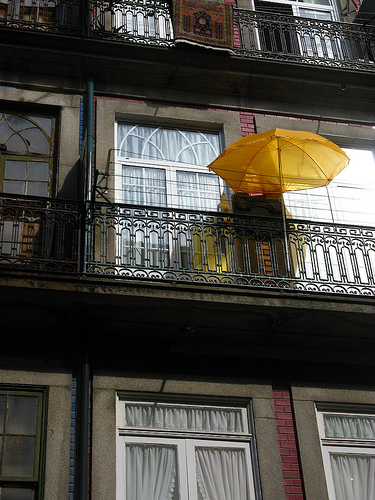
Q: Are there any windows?
A: Yes, there is a window.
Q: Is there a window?
A: Yes, there is a window.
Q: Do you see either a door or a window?
A: Yes, there is a window.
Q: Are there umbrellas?
A: Yes, there is an umbrella.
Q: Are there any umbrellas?
A: Yes, there is an umbrella.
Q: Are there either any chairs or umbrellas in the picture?
A: Yes, there is an umbrella.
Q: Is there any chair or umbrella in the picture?
A: Yes, there is an umbrella.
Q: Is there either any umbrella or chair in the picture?
A: Yes, there is an umbrella.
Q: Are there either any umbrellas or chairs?
A: Yes, there is an umbrella.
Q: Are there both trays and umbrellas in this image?
A: No, there is an umbrella but no trays.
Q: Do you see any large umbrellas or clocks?
A: Yes, there is a large umbrella.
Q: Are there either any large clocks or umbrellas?
A: Yes, there is a large umbrella.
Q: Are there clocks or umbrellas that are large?
A: Yes, the umbrella is large.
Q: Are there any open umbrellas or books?
A: Yes, there is an open umbrella.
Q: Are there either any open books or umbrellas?
A: Yes, there is an open umbrella.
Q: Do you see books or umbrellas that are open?
A: Yes, the umbrella is open.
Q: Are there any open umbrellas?
A: Yes, there is an open umbrella.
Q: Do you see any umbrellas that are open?
A: Yes, there is an umbrella that is open.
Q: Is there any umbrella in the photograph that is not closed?
A: Yes, there is a open umbrella.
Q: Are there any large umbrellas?
A: Yes, there is a large umbrella.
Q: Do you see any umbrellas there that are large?
A: Yes, there is an umbrella that is large.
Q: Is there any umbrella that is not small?
A: Yes, there is a large umbrella.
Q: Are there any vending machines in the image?
A: No, there are no vending machines.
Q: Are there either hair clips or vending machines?
A: No, there are no vending machines or hair clips.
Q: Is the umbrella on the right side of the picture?
A: Yes, the umbrella is on the right of the image.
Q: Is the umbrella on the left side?
A: No, the umbrella is on the right of the image.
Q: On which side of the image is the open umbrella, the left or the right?
A: The umbrella is on the right of the image.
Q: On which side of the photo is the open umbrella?
A: The umbrella is on the right of the image.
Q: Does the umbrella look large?
A: Yes, the umbrella is large.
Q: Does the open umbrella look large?
A: Yes, the umbrella is large.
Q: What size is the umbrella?
A: The umbrella is large.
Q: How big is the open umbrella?
A: The umbrella is large.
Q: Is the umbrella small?
A: No, the umbrella is large.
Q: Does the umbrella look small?
A: No, the umbrella is large.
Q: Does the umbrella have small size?
A: No, the umbrella is large.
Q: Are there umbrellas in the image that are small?
A: No, there is an umbrella but it is large.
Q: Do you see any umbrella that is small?
A: No, there is an umbrella but it is large.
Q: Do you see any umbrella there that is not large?
A: No, there is an umbrella but it is large.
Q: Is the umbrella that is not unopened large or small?
A: The umbrella is large.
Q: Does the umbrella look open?
A: Yes, the umbrella is open.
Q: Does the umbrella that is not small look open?
A: Yes, the umbrella is open.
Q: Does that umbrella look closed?
A: No, the umbrella is open.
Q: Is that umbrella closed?
A: No, the umbrella is open.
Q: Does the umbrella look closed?
A: No, the umbrella is open.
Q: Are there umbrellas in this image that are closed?
A: No, there is an umbrella but it is open.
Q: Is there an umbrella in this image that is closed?
A: No, there is an umbrella but it is open.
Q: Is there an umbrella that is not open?
A: No, there is an umbrella but it is open.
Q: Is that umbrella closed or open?
A: The umbrella is open.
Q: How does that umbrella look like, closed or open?
A: The umbrella is open.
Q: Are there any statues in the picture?
A: No, there are no statues.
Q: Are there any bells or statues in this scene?
A: No, there are no statues or bells.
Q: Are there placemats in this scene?
A: No, there are no placemats.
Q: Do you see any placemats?
A: No, there are no placemats.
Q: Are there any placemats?
A: No, there are no placemats.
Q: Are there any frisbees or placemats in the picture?
A: No, there are no placemats or frisbees.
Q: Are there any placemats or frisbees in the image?
A: No, there are no placemats or frisbees.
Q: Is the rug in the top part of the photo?
A: Yes, the rug is in the top of the image.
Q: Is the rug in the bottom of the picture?
A: No, the rug is in the top of the image.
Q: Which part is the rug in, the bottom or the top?
A: The rug is in the top of the image.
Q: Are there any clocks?
A: No, there are no clocks.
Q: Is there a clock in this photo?
A: No, there are no clocks.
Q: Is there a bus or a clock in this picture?
A: No, there are no clocks or buses.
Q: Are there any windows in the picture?
A: Yes, there are windows.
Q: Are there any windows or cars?
A: Yes, there are windows.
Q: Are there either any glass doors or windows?
A: Yes, there are glass windows.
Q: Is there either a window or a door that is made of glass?
A: Yes, the windows are made of glass.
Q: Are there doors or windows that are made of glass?
A: Yes, the windows are made of glass.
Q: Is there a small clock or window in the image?
A: Yes, there are small windows.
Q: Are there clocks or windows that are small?
A: Yes, the windows are small.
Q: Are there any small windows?
A: Yes, there are small windows.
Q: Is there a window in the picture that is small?
A: Yes, there are windows that are small.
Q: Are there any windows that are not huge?
A: Yes, there are small windows.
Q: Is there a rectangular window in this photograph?
A: Yes, there are rectangular windows.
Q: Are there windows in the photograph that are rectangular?
A: Yes, there are windows that are rectangular.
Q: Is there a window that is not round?
A: Yes, there are rectangular windows.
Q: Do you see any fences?
A: No, there are no fences.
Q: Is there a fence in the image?
A: No, there are no fences.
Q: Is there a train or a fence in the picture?
A: No, there are no fences or trains.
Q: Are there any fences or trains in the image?
A: No, there are no fences or trains.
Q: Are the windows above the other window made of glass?
A: Yes, the windows are made of glass.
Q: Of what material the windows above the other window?
A: The windows are made of glass.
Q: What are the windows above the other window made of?
A: The windows are made of glass.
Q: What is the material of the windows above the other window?
A: The windows are made of glass.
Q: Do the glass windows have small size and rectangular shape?
A: Yes, the windows are small and rectangular.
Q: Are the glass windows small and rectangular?
A: Yes, the windows are small and rectangular.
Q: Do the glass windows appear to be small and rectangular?
A: Yes, the windows are small and rectangular.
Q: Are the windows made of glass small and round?
A: No, the windows are small but rectangular.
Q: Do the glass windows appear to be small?
A: Yes, the windows are small.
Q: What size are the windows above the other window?
A: The windows are small.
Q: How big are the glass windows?
A: The windows are small.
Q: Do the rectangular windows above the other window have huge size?
A: No, the windows are small.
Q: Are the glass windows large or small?
A: The windows are small.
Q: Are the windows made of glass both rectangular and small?
A: Yes, the windows are rectangular and small.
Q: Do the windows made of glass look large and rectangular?
A: No, the windows are rectangular but small.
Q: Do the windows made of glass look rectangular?
A: Yes, the windows are rectangular.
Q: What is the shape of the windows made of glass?
A: The windows are rectangular.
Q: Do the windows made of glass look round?
A: No, the windows are rectangular.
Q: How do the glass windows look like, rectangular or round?
A: The windows are rectangular.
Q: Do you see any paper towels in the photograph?
A: No, there are no paper towels.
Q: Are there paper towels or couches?
A: No, there are no paper towels or couches.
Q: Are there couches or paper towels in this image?
A: No, there are no paper towels or couches.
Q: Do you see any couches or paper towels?
A: No, there are no paper towels or couches.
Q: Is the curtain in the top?
A: No, the curtain is in the bottom of the image.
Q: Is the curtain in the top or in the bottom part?
A: The curtain is in the bottom of the image.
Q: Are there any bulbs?
A: No, there are no bulbs.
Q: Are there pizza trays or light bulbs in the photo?
A: No, there are no light bulbs or pizza trays.